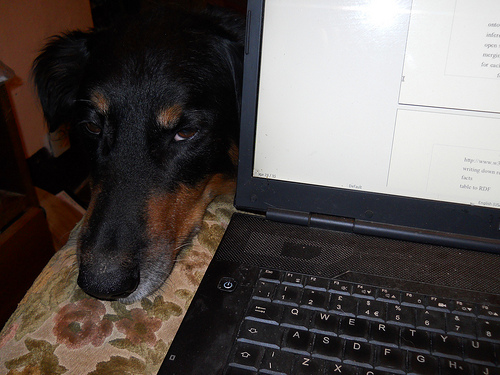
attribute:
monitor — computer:
[250, 3, 497, 216]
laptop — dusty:
[209, 211, 451, 346]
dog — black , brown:
[35, 65, 197, 296]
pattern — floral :
[14, 295, 139, 373]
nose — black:
[88, 266, 140, 298]